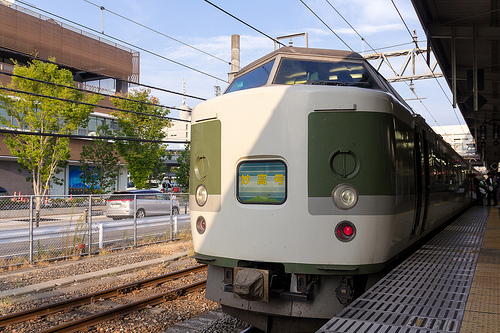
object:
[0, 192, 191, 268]
fence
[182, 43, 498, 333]
train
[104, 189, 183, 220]
minivan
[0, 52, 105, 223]
tree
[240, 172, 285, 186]
writing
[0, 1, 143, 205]
building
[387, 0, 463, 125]
wire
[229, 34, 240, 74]
smoke stack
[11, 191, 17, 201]
cone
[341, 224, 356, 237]
light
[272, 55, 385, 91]
window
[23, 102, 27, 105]
leaf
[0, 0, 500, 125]
sky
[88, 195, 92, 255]
pole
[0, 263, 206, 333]
track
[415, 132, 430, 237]
door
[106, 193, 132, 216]
rear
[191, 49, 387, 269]
front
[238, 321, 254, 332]
tracks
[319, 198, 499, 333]
walkway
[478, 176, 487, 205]
passenger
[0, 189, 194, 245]
street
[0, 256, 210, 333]
gravel